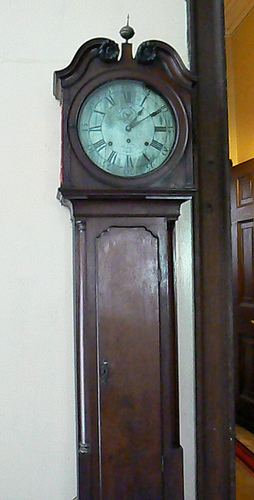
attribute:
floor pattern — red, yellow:
[233, 420, 253, 499]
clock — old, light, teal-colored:
[59, 53, 233, 205]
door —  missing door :
[116, 395, 161, 496]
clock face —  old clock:
[74, 75, 185, 180]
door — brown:
[231, 158, 253, 432]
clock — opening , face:
[75, 77, 177, 177]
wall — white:
[4, 46, 50, 267]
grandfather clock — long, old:
[52, 14, 205, 498]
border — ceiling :
[227, 2, 249, 34]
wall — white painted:
[211, 9, 250, 162]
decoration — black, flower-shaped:
[98, 40, 118, 61]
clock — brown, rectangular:
[48, 16, 193, 490]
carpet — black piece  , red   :
[235, 436, 253, 472]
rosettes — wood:
[93, 36, 123, 65]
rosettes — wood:
[132, 39, 159, 62]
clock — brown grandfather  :
[52, 29, 200, 498]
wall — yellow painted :
[222, 0, 252, 166]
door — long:
[83, 216, 168, 494]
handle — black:
[102, 359, 107, 384]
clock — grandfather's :
[86, 84, 185, 164]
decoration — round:
[116, 22, 134, 41]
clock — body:
[55, 7, 207, 497]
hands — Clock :
[126, 107, 160, 130]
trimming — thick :
[222, 1, 244, 35]